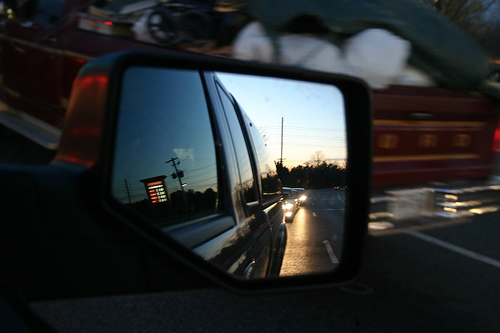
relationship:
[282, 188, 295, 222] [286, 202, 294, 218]
car has headlights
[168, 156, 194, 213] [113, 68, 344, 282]
electric pole in mirror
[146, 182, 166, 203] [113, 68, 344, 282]
sign in mirror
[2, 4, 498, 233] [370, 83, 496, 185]
truck has tailgate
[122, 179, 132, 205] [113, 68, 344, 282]
electric pole in mirror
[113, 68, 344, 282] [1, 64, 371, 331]
mirror on vehicle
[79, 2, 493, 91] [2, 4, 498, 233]
items are in truck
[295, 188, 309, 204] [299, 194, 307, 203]
car has headlights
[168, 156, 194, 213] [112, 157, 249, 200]
electric pole has wires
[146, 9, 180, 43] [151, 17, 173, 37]
wheel has spokes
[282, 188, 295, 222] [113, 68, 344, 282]
car in mirror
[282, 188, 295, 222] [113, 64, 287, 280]
car behind car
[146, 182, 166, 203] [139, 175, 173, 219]
sign belongs to gas station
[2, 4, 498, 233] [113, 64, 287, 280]
truck in front of car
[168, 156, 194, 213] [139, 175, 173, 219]
electric pole near gas station